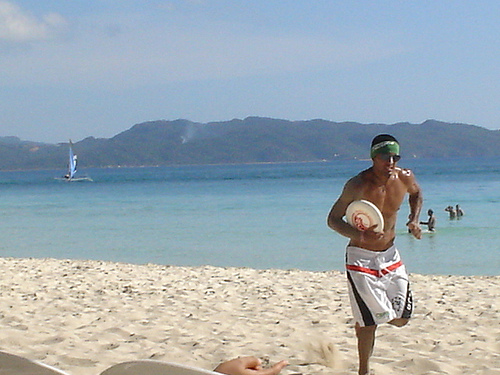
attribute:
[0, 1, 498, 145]
sky — blue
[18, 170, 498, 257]
water — calm, blue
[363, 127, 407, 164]
visor — green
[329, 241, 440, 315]
trunks — white, red, black, swim trunks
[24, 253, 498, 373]
beach — sandy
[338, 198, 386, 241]
frisbee — white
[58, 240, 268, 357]
sandy surface — uneven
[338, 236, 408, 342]
shorts — white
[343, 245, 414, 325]
swimsuit — white, black, red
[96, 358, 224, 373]
chair — plastic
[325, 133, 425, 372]
man — shirtless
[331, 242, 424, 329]
shorts — white, red, and black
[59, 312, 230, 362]
sand — white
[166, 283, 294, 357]
sand — white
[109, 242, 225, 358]
sand — white